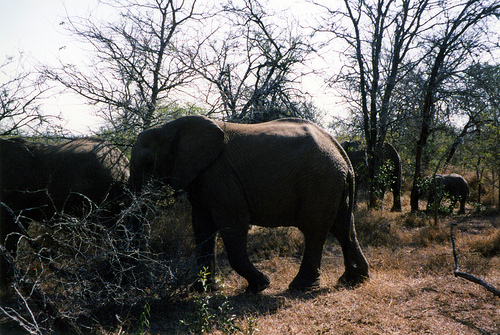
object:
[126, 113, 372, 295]
elephant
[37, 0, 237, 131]
tree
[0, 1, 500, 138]
sky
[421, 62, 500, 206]
trees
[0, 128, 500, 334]
ground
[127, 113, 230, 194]
head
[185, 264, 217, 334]
plant